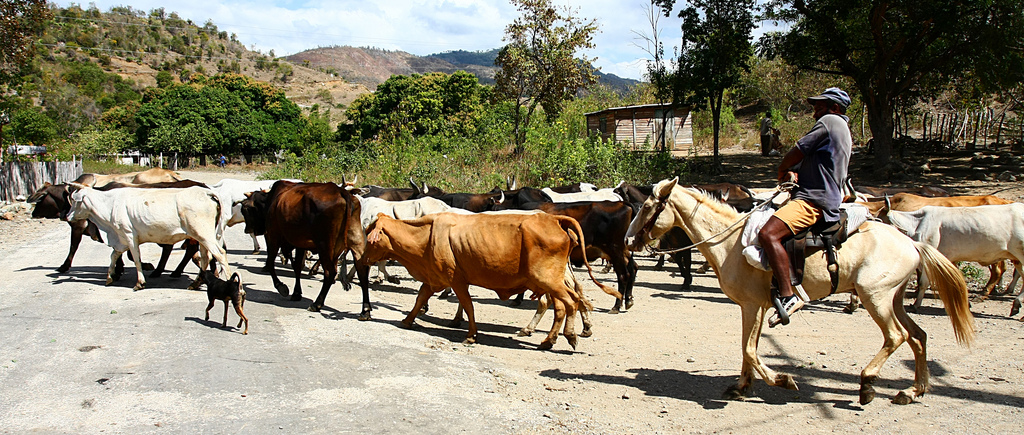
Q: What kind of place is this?
A: It is a field.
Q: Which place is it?
A: It is a field.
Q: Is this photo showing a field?
A: Yes, it is showing a field.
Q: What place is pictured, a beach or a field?
A: It is a field.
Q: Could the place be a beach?
A: No, it is a field.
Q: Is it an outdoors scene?
A: Yes, it is outdoors.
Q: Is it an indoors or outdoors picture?
A: It is outdoors.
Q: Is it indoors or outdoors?
A: It is outdoors.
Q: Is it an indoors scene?
A: No, it is outdoors.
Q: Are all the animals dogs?
A: No, there are both horses and dogs.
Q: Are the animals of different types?
A: Yes, they are horses and dogs.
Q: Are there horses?
A: Yes, there is a horse.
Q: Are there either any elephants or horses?
A: Yes, there is a horse.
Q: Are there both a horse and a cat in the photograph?
A: No, there is a horse but no cats.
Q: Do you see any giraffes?
A: No, there are no giraffes.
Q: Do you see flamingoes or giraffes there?
A: No, there are no giraffes or flamingoes.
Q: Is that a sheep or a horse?
A: That is a horse.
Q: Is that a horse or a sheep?
A: That is a horse.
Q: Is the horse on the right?
A: Yes, the horse is on the right of the image.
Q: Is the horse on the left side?
A: No, the horse is on the right of the image.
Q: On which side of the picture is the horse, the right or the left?
A: The horse is on the right of the image.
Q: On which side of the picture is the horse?
A: The horse is on the right of the image.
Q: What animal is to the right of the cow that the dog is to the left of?
A: The animal is a horse.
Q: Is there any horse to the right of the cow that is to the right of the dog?
A: Yes, there is a horse to the right of the cow.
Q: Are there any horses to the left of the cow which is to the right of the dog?
A: No, the horse is to the right of the cow.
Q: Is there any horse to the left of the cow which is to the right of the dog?
A: No, the horse is to the right of the cow.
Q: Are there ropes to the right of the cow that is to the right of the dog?
A: No, there is a horse to the right of the cow.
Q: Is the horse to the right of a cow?
A: Yes, the horse is to the right of a cow.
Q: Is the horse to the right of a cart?
A: No, the horse is to the right of a cow.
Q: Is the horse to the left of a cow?
A: No, the horse is to the right of a cow.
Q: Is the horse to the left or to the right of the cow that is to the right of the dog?
A: The horse is to the right of the cow.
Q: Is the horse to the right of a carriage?
A: No, the horse is to the right of the cow.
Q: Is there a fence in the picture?
A: Yes, there is a fence.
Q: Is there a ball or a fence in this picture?
A: Yes, there is a fence.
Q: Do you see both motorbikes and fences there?
A: No, there is a fence but no motorcycles.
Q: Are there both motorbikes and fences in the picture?
A: No, there is a fence but no motorcycles.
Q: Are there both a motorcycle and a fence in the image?
A: No, there is a fence but no motorcycles.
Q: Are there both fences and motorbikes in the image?
A: No, there is a fence but no motorcycles.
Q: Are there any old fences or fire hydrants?
A: Yes, there is an old fence.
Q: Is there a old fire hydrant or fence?
A: Yes, there is an old fence.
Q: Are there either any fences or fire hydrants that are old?
A: Yes, the fence is old.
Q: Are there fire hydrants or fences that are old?
A: Yes, the fence is old.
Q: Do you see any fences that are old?
A: Yes, there is an old fence.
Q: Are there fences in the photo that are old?
A: Yes, there is a fence that is old.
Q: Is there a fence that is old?
A: Yes, there is a fence that is old.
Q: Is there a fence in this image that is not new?
A: Yes, there is a old fence.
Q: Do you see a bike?
A: No, there are no bikes.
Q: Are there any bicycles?
A: No, there are no bicycles.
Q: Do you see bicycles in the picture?
A: No, there are no bicycles.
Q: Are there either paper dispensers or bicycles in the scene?
A: No, there are no bicycles or paper dispensers.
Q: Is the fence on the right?
A: Yes, the fence is on the right of the image.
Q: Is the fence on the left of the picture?
A: No, the fence is on the right of the image.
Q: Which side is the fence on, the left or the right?
A: The fence is on the right of the image.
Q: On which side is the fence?
A: The fence is on the right of the image.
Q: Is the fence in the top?
A: Yes, the fence is in the top of the image.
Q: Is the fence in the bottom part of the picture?
A: No, the fence is in the top of the image.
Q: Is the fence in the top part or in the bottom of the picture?
A: The fence is in the top of the image.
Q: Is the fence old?
A: Yes, the fence is old.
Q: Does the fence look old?
A: Yes, the fence is old.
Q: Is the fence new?
A: No, the fence is old.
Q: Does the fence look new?
A: No, the fence is old.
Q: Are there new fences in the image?
A: No, there is a fence but it is old.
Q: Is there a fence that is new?
A: No, there is a fence but it is old.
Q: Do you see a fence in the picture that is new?
A: No, there is a fence but it is old.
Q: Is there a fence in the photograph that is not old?
A: No, there is a fence but it is old.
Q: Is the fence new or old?
A: The fence is old.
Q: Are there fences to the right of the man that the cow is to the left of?
A: Yes, there is a fence to the right of the man.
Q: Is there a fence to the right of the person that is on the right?
A: Yes, there is a fence to the right of the man.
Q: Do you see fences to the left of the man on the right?
A: No, the fence is to the right of the man.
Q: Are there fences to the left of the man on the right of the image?
A: No, the fence is to the right of the man.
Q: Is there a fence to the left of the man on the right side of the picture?
A: No, the fence is to the right of the man.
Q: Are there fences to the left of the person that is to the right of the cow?
A: No, the fence is to the right of the man.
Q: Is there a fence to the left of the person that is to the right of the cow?
A: No, the fence is to the right of the man.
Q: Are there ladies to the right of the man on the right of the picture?
A: No, there is a fence to the right of the man.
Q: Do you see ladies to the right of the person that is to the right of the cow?
A: No, there is a fence to the right of the man.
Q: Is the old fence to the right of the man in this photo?
A: Yes, the fence is to the right of the man.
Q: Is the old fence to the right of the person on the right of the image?
A: Yes, the fence is to the right of the man.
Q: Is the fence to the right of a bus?
A: No, the fence is to the right of the man.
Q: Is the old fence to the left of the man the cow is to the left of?
A: No, the fence is to the right of the man.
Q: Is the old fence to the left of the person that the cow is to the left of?
A: No, the fence is to the right of the man.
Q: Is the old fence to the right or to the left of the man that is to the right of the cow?
A: The fence is to the right of the man.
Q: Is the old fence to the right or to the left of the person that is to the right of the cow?
A: The fence is to the right of the man.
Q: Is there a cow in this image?
A: Yes, there is a cow.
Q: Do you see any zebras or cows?
A: Yes, there is a cow.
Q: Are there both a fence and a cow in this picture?
A: Yes, there are both a cow and a fence.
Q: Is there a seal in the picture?
A: No, there are no seals.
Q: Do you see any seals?
A: No, there are no seals.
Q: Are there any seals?
A: No, there are no seals.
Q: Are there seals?
A: No, there are no seals.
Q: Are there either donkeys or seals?
A: No, there are no seals or donkeys.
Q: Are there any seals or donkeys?
A: No, there are no seals or donkeys.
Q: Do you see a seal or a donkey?
A: No, there are no seals or donkeys.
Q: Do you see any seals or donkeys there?
A: No, there are no seals or donkeys.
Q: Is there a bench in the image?
A: No, there are no benches.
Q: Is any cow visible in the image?
A: Yes, there is a cow.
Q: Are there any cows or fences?
A: Yes, there is a cow.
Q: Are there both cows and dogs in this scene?
A: Yes, there are both a cow and a dog.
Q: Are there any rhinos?
A: No, there are no rhinos.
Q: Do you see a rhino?
A: No, there are no rhinos.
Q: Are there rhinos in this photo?
A: No, there are no rhinos.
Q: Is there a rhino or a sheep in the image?
A: No, there are no rhinos or sheep.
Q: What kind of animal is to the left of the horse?
A: The animal is a cow.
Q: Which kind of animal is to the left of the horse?
A: The animal is a cow.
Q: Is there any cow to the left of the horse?
A: Yes, there is a cow to the left of the horse.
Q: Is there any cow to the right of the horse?
A: No, the cow is to the left of the horse.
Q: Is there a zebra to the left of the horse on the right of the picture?
A: No, there is a cow to the left of the horse.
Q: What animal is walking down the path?
A: The animal is a cow.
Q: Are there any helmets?
A: No, there are no helmets.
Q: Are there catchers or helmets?
A: No, there are no helmets or catchers.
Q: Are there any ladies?
A: No, there are no ladies.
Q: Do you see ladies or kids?
A: No, there are no ladies or kids.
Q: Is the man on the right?
A: Yes, the man is on the right of the image.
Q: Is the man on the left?
A: No, the man is on the right of the image.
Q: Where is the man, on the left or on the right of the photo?
A: The man is on the right of the image.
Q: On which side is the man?
A: The man is on the right of the image.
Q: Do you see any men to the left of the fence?
A: Yes, there is a man to the left of the fence.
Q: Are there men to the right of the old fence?
A: No, the man is to the left of the fence.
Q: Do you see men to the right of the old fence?
A: No, the man is to the left of the fence.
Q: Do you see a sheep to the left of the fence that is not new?
A: No, there is a man to the left of the fence.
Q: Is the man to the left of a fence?
A: Yes, the man is to the left of a fence.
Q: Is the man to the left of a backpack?
A: No, the man is to the left of a fence.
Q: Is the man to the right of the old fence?
A: No, the man is to the left of the fence.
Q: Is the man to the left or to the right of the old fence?
A: The man is to the left of the fence.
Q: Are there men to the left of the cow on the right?
A: Yes, there is a man to the left of the cow.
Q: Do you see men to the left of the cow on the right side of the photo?
A: Yes, there is a man to the left of the cow.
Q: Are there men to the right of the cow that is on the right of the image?
A: No, the man is to the left of the cow.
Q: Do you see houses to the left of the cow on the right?
A: No, there is a man to the left of the cow.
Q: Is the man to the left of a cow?
A: Yes, the man is to the left of a cow.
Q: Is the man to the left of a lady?
A: No, the man is to the left of a cow.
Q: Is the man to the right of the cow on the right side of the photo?
A: No, the man is to the left of the cow.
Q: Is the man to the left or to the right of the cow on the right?
A: The man is to the left of the cow.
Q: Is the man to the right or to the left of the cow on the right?
A: The man is to the left of the cow.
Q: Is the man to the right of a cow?
A: Yes, the man is to the right of a cow.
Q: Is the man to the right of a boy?
A: No, the man is to the right of a cow.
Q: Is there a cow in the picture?
A: Yes, there is a cow.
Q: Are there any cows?
A: Yes, there is a cow.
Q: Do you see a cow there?
A: Yes, there is a cow.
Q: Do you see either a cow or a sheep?
A: Yes, there is a cow.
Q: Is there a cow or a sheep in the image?
A: Yes, there is a cow.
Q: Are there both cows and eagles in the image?
A: No, there is a cow but no eagles.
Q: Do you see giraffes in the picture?
A: No, there are no giraffes.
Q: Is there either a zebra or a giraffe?
A: No, there are no giraffes or zebras.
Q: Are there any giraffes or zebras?
A: No, there are no giraffes or zebras.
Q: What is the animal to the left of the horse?
A: The animal is a cow.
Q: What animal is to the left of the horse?
A: The animal is a cow.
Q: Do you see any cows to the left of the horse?
A: Yes, there is a cow to the left of the horse.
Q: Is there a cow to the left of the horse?
A: Yes, there is a cow to the left of the horse.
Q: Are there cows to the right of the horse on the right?
A: No, the cow is to the left of the horse.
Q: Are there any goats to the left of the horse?
A: No, there is a cow to the left of the horse.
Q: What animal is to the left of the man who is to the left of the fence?
A: The animal is a cow.